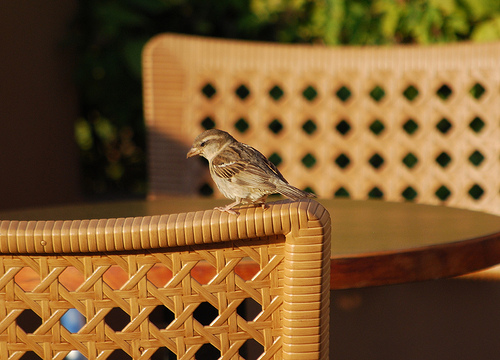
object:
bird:
[186, 127, 319, 216]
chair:
[0, 198, 334, 360]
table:
[0, 196, 500, 302]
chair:
[139, 29, 500, 279]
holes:
[192, 301, 222, 329]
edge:
[331, 232, 496, 289]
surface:
[0, 196, 500, 263]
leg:
[243, 287, 377, 359]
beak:
[185, 147, 201, 160]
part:
[215, 161, 253, 179]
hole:
[232, 255, 262, 284]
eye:
[200, 140, 207, 147]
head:
[186, 127, 235, 161]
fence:
[74, 35, 147, 197]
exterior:
[0, 0, 499, 360]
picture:
[0, 195, 499, 360]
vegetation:
[77, 0, 499, 44]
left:
[0, 0, 177, 360]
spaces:
[99, 263, 117, 281]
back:
[0, 0, 499, 34]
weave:
[0, 198, 332, 255]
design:
[139, 261, 177, 290]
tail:
[273, 183, 318, 202]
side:
[210, 147, 275, 200]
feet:
[213, 198, 239, 215]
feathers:
[225, 162, 238, 164]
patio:
[0, 36, 497, 360]